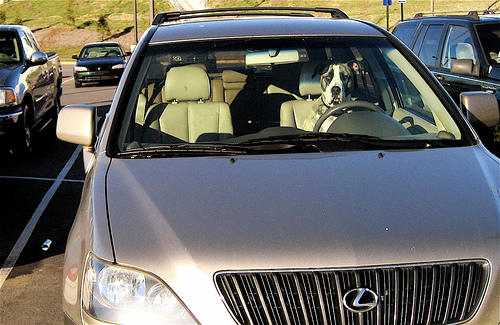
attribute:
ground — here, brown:
[0, 65, 126, 324]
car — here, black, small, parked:
[72, 43, 132, 86]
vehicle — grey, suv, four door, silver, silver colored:
[57, 6, 499, 322]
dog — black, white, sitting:
[301, 59, 364, 130]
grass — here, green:
[2, 0, 500, 60]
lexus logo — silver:
[341, 287, 380, 314]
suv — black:
[392, 10, 499, 155]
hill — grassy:
[2, 0, 500, 62]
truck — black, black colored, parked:
[1, 24, 61, 157]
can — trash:
[40, 239, 49, 251]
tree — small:
[96, 13, 112, 42]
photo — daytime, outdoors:
[0, 1, 499, 324]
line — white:
[0, 117, 100, 282]